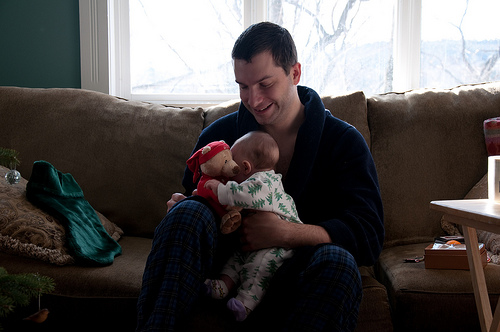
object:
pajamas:
[181, 136, 230, 199]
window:
[127, 0, 498, 94]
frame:
[80, 0, 420, 111]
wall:
[0, 0, 83, 89]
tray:
[429, 195, 499, 330]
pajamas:
[206, 167, 301, 313]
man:
[131, 18, 393, 330]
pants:
[125, 199, 360, 330]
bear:
[190, 133, 243, 231]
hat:
[181, 136, 231, 176]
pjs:
[206, 167, 303, 312]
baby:
[200, 127, 306, 317]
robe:
[127, 80, 395, 330]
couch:
[2, 82, 498, 329]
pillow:
[0, 179, 126, 266]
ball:
[1, 167, 33, 193]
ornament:
[17, 270, 47, 310]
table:
[430, 180, 495, 297]